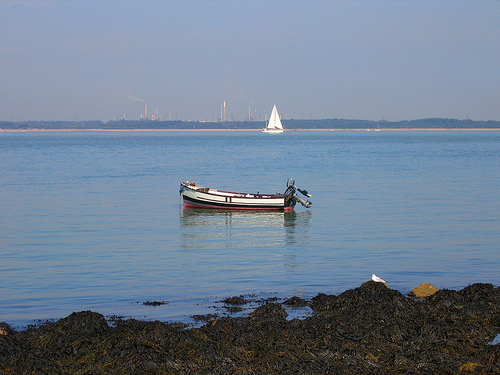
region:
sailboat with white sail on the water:
[257, 103, 287, 137]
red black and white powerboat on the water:
[167, 173, 314, 220]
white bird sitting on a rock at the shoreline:
[360, 268, 395, 290]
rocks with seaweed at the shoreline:
[0, 283, 305, 368]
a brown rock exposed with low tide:
[405, 278, 450, 305]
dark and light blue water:
[2, 130, 178, 292]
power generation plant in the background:
[101, 93, 262, 128]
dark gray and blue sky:
[15, 8, 480, 101]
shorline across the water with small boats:
[0, 122, 487, 138]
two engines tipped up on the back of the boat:
[277, 175, 318, 216]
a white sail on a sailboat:
[265, 103, 274, 130]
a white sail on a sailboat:
[275, 104, 282, 129]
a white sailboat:
[263, 100, 283, 133]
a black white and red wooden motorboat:
[180, 175, 312, 223]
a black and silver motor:
[282, 186, 309, 204]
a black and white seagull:
[369, 268, 387, 287]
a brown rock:
[408, 278, 439, 299]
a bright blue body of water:
[3, 131, 493, 329]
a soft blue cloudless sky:
[2, 4, 498, 119]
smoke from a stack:
[125, 91, 146, 102]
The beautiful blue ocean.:
[0, 127, 498, 330]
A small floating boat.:
[178, 176, 312, 215]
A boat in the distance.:
[261, 102, 284, 134]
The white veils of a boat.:
[266, 100, 283, 129]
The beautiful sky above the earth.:
[0, 0, 498, 116]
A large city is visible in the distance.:
[0, 98, 497, 128]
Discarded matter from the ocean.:
[1, 274, 498, 373]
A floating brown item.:
[410, 280, 440, 298]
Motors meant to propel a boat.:
[283, 176, 313, 211]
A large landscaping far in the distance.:
[0, 116, 497, 127]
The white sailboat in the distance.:
[262, 108, 293, 139]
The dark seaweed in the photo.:
[11, 286, 498, 371]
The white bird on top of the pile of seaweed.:
[368, 265, 394, 285]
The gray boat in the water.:
[182, 175, 317, 207]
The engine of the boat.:
[287, 177, 314, 210]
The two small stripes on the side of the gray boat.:
[225, 193, 235, 205]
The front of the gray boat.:
[179, 178, 193, 195]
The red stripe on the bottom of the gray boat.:
[177, 198, 296, 220]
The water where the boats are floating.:
[4, 131, 499, 323]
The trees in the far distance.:
[14, 92, 496, 135]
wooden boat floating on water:
[156, 175, 332, 229]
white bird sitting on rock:
[352, 262, 393, 296]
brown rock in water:
[404, 271, 446, 306]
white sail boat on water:
[259, 91, 291, 136]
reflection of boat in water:
[182, 209, 292, 244]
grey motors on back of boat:
[278, 173, 333, 208]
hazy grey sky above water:
[28, 3, 490, 84]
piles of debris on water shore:
[339, 311, 456, 373]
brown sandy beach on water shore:
[382, 121, 497, 133]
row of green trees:
[21, 116, 203, 128]